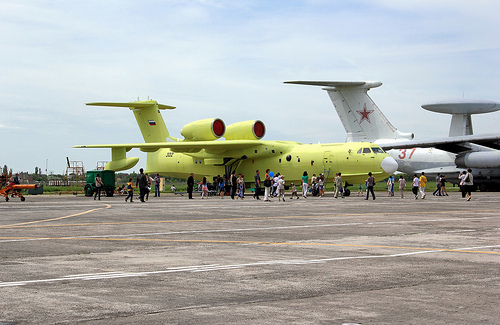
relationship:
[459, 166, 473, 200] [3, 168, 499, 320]
person at airport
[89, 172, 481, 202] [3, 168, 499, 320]
people at airport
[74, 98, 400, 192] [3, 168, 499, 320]
plane at airport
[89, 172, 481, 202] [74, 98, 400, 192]
people by plane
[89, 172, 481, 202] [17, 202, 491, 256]
people on tarmac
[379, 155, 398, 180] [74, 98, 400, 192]
nose of plane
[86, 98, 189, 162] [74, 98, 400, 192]
tail of plane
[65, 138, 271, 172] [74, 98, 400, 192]
wing of plane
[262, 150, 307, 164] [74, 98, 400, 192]
windows on plane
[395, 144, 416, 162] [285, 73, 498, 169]
number on plane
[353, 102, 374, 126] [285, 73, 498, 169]
star on plane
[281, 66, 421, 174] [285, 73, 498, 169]
tail of plane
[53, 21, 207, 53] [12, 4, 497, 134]
clouds in sky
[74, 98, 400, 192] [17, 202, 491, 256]
plane on tarmac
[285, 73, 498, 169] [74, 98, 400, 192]
plane next to plane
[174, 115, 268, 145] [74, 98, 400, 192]
engines on plane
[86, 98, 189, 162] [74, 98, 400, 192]
tail on plane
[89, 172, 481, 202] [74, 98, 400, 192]
people around plane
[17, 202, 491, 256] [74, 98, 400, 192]
tarmac under plane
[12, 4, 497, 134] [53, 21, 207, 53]
sky with clouds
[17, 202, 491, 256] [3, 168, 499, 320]
tarmac at airport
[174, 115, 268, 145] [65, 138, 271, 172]
engines on wing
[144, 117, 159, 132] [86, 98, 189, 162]
flag on tail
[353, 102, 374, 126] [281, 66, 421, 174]
star on tail